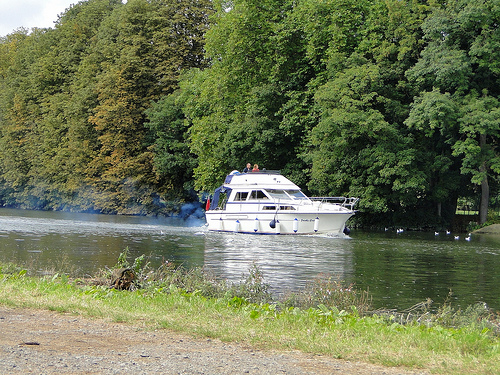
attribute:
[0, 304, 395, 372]
road — gravel, light brown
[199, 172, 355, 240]
boat — white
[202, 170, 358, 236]
boat — white , green 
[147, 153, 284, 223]
smoke —  gray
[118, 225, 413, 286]
water — green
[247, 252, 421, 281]
water — reflection 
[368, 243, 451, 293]
water — ducks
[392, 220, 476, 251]
ducks — white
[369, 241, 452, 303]
water —  ruffled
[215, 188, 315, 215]
rails — boat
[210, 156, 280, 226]
people — boat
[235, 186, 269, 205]
windows — boat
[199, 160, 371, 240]
boat — water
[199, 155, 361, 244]
boat — white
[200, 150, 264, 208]
people — standing 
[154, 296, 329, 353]
grass — green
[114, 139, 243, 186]
smoke — boat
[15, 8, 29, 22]
sky — clear, blue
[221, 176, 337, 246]
boat — white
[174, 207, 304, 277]
water — narrow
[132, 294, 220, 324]
grass — tall, green